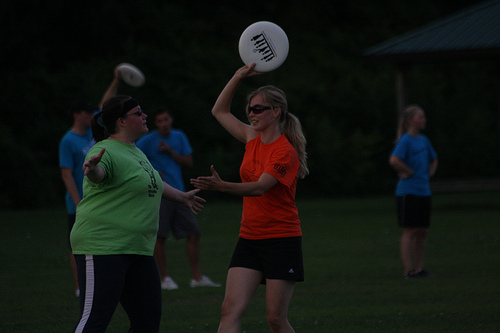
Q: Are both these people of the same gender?
A: Yes, all the people are female.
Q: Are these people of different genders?
A: No, all the people are female.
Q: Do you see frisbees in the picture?
A: Yes, there is a frisbee.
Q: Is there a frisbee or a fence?
A: Yes, there is a frisbee.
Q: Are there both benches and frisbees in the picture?
A: No, there is a frisbee but no benches.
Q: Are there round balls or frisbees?
A: Yes, there is a round frisbee.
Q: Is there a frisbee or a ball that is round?
A: Yes, the frisbee is round.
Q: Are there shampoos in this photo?
A: No, there are no shampoos.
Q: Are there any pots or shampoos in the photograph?
A: No, there are no shampoos or pots.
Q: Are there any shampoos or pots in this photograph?
A: No, there are no shampoos or pots.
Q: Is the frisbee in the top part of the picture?
A: Yes, the frisbee is in the top of the image.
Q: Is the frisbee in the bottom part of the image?
A: No, the frisbee is in the top of the image.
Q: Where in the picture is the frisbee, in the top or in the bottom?
A: The frisbee is in the top of the image.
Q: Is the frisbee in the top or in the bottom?
A: The frisbee is in the top of the image.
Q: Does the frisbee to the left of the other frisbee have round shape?
A: Yes, the frisbee is round.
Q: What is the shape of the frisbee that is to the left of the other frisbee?
A: The frisbee is round.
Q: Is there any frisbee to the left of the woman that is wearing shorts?
A: Yes, there is a frisbee to the left of the woman.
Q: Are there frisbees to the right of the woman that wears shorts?
A: No, the frisbee is to the left of the woman.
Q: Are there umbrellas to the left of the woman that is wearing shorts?
A: No, there is a frisbee to the left of the woman.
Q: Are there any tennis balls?
A: No, there are no tennis balls.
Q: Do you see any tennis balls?
A: No, there are no tennis balls.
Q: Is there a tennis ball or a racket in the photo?
A: No, there are no tennis balls or rackets.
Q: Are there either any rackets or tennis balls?
A: No, there are no tennis balls or rackets.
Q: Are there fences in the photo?
A: No, there are no fences.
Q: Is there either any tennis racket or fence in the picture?
A: No, there are no fences or rackets.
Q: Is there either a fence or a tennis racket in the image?
A: No, there are no fences or rackets.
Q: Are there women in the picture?
A: Yes, there is a woman.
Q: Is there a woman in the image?
A: Yes, there is a woman.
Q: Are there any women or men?
A: Yes, there is a woman.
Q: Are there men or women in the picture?
A: Yes, there is a woman.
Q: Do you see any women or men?
A: Yes, there is a woman.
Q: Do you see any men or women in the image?
A: Yes, there is a woman.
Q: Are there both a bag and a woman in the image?
A: No, there is a woman but no bags.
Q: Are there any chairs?
A: No, there are no chairs.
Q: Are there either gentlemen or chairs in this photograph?
A: No, there are no chairs or gentlemen.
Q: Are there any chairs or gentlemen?
A: No, there are no chairs or gentlemen.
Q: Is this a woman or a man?
A: This is a woman.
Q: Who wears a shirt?
A: The woman wears a shirt.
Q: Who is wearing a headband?
A: The woman is wearing a headband.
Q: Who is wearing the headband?
A: The woman is wearing a headband.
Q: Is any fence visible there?
A: No, there are no fences.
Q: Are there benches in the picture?
A: No, there are no benches.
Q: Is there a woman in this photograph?
A: Yes, there is a woman.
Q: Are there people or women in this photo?
A: Yes, there is a woman.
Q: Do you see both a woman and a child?
A: No, there is a woman but no children.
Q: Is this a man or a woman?
A: This is a woman.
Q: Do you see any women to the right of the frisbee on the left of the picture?
A: Yes, there is a woman to the right of the frisbee.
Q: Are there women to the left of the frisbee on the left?
A: No, the woman is to the right of the frisbee.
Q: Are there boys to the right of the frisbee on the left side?
A: No, there is a woman to the right of the frisbee.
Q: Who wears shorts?
A: The woman wears shorts.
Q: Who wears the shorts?
A: The woman wears shorts.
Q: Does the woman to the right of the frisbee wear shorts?
A: Yes, the woman wears shorts.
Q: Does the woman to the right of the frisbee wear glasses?
A: No, the woman wears shorts.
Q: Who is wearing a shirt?
A: The woman is wearing a shirt.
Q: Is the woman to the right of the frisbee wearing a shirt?
A: Yes, the woman is wearing a shirt.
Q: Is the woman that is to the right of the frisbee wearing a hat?
A: No, the woman is wearing a shirt.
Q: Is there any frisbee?
A: Yes, there is a frisbee.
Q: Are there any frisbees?
A: Yes, there is a frisbee.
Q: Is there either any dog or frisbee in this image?
A: Yes, there is a frisbee.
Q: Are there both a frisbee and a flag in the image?
A: No, there is a frisbee but no flags.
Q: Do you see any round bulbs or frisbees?
A: Yes, there is a round frisbee.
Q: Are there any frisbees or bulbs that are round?
A: Yes, the frisbee is round.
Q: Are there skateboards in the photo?
A: No, there are no skateboards.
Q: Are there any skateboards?
A: No, there are no skateboards.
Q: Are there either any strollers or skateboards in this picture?
A: No, there are no skateboards or strollers.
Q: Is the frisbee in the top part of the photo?
A: Yes, the frisbee is in the top of the image.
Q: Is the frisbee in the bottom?
A: No, the frisbee is in the top of the image.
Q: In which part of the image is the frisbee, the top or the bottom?
A: The frisbee is in the top of the image.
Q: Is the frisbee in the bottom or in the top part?
A: The frisbee is in the top of the image.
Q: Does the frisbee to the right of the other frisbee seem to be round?
A: Yes, the frisbee is round.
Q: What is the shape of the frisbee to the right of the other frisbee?
A: The frisbee is round.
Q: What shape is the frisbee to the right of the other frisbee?
A: The frisbee is round.